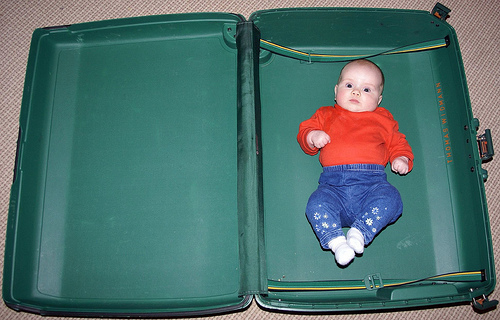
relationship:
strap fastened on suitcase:
[257, 31, 449, 63] [24, 21, 482, 286]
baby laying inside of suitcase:
[302, 57, 405, 253] [24, 21, 482, 286]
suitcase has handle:
[24, 21, 482, 286] [482, 129, 496, 157]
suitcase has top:
[24, 21, 482, 286] [9, 28, 257, 316]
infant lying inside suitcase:
[302, 57, 405, 253] [24, 21, 482, 286]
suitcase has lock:
[24, 21, 482, 286] [471, 117, 495, 178]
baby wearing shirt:
[302, 57, 405, 253] [297, 108, 423, 162]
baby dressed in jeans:
[302, 57, 405, 253] [303, 167, 402, 264]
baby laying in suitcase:
[302, 57, 405, 253] [24, 21, 482, 286]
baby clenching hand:
[302, 57, 405, 253] [310, 129, 331, 149]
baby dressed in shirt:
[302, 57, 405, 253] [297, 108, 423, 162]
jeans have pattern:
[303, 167, 402, 264] [313, 202, 381, 238]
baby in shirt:
[302, 57, 405, 253] [297, 108, 423, 162]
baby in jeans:
[302, 57, 405, 253] [303, 167, 402, 264]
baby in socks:
[302, 57, 405, 253] [340, 238, 358, 266]